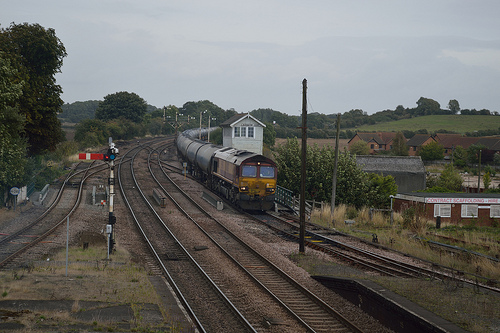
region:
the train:
[213, 150, 273, 207]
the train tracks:
[276, 275, 313, 316]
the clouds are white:
[175, 40, 261, 79]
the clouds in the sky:
[170, 52, 247, 82]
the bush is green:
[307, 156, 337, 190]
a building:
[413, 187, 498, 219]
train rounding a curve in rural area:
[10, 10, 482, 322]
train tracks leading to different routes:
[5, 125, 477, 325]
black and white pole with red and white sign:
[73, 137, 118, 247]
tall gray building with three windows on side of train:
[173, 103, 278, 208]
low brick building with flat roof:
[389, 186, 496, 227]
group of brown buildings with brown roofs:
[341, 125, 495, 161]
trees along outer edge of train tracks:
[0, 19, 265, 199]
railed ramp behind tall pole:
[270, 75, 325, 247]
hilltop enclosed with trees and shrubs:
[307, 89, 496, 139]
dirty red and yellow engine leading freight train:
[172, 121, 280, 212]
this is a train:
[166, 93, 288, 220]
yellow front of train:
[231, 163, 280, 202]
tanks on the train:
[158, 96, 225, 176]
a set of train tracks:
[103, 175, 311, 323]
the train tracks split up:
[0, 138, 213, 328]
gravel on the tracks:
[148, 185, 285, 318]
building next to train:
[211, 98, 276, 188]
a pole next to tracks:
[61, 121, 134, 267]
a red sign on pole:
[72, 139, 108, 165]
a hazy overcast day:
[6, 5, 491, 293]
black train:
[172, 119, 287, 216]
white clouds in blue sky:
[77, 21, 141, 66]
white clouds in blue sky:
[422, 22, 447, 50]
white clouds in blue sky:
[346, 31, 367, 53]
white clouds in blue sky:
[242, 21, 279, 62]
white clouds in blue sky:
[352, 18, 373, 52]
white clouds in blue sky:
[342, 35, 382, 56]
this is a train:
[163, 97, 303, 211]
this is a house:
[379, 178, 499, 242]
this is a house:
[339, 143, 431, 208]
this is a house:
[331, 122, 408, 164]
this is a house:
[439, 137, 489, 164]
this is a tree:
[274, 126, 393, 231]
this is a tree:
[5, 15, 70, 186]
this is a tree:
[83, 79, 145, 159]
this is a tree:
[399, 89, 448, 133]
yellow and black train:
[180, 112, 280, 214]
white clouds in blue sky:
[442, 21, 497, 66]